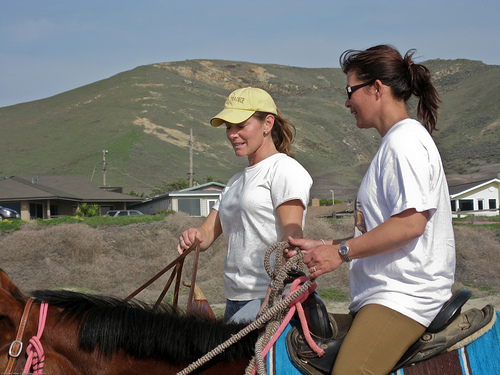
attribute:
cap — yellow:
[211, 86, 278, 128]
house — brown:
[1, 173, 145, 219]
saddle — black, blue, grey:
[286, 288, 470, 374]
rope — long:
[173, 240, 316, 374]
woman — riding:
[284, 44, 457, 374]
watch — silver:
[339, 239, 351, 266]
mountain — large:
[0, 58, 498, 219]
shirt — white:
[349, 118, 456, 326]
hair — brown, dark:
[340, 44, 440, 135]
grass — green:
[0, 212, 166, 232]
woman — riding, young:
[176, 86, 312, 324]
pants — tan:
[330, 303, 443, 374]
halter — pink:
[21, 297, 51, 373]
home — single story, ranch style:
[447, 178, 500, 216]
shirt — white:
[213, 153, 313, 301]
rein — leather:
[115, 236, 202, 313]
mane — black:
[27, 289, 260, 350]